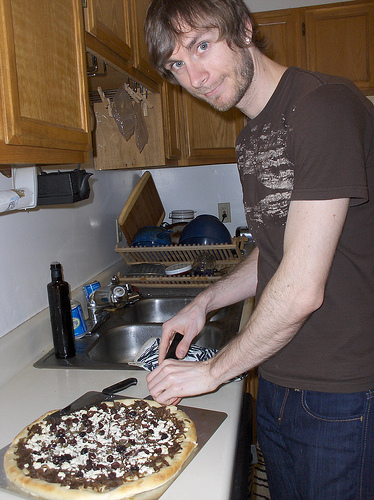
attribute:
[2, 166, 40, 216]
dispenser — white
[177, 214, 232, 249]
bowl — blue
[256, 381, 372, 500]
jeans — denim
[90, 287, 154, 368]
sink — steel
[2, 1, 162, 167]
cabinets — oak, brown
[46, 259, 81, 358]
bottle — black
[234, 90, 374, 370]
shirt — brown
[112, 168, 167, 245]
cutting-board — brown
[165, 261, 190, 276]
lid — white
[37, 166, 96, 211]
kettle — hanging, black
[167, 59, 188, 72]
eyes — blue